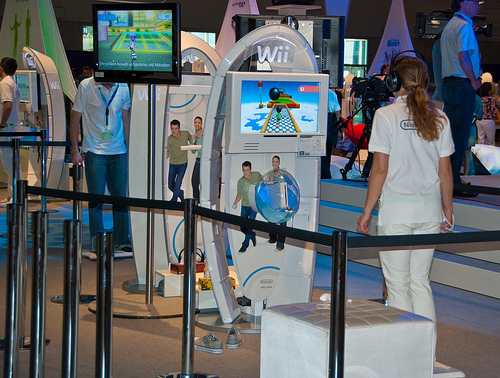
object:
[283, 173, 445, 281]
station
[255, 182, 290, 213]
wii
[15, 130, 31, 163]
tv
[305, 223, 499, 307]
cube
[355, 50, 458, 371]
woman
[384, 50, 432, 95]
headphones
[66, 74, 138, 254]
guy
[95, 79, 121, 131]
lanyard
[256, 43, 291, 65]
lettering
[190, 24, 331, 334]
console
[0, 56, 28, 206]
man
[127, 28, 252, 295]
console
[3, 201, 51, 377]
pair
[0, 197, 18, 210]
shoes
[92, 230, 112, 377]
metal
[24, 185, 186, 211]
straps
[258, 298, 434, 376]
bench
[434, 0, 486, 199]
man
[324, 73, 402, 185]
camera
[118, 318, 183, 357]
carpet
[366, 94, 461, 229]
shirt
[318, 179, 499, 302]
stairs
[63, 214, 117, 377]
person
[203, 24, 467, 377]
person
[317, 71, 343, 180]
man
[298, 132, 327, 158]
sign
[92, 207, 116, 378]
pole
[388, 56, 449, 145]
pony tail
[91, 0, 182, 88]
monitor